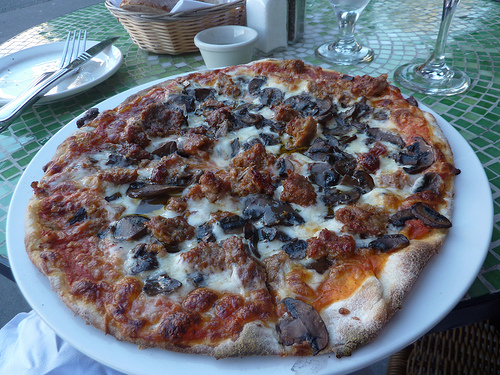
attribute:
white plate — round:
[5, 80, 494, 374]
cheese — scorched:
[73, 271, 106, 308]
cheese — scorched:
[69, 130, 112, 141]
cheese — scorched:
[280, 52, 320, 84]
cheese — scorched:
[361, 71, 393, 106]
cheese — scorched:
[165, 302, 202, 349]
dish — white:
[6, 67, 491, 373]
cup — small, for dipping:
[189, 23, 262, 60]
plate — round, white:
[1, 33, 101, 100]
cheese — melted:
[193, 197, 221, 221]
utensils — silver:
[0, 31, 117, 125]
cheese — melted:
[88, 80, 426, 298]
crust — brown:
[328, 249, 420, 350]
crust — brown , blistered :
[333, 260, 418, 344]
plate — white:
[7, 64, 492, 374]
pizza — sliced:
[129, 103, 470, 370]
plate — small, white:
[2, 40, 121, 105]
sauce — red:
[160, 195, 309, 288]